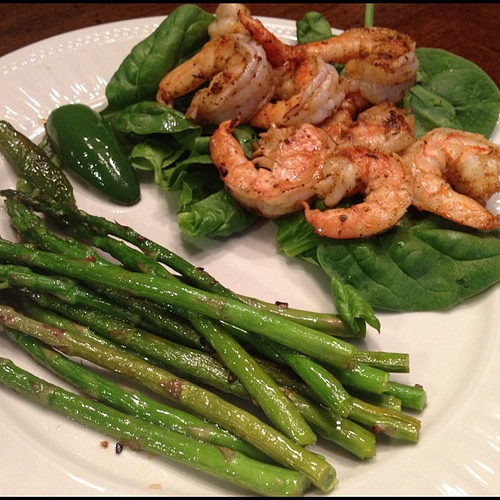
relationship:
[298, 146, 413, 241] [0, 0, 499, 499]
shrimp on plate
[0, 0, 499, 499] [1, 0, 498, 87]
plate on table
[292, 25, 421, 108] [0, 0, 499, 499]
shrimp on plate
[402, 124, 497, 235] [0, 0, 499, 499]
shrimp on plate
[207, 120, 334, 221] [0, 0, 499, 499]
shrimp on plate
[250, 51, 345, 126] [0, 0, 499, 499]
shrimp on plate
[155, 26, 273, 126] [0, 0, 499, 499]
shrimp on plate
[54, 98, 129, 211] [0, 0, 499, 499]
pepper on plate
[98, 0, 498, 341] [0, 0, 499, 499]
spinach on plate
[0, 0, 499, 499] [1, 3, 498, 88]
plate on surface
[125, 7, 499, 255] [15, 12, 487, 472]
shrimp on plate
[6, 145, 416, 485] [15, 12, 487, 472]
veggies on plate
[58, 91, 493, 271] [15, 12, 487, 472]
veggies on plate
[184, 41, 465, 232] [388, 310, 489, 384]
shrimps on plate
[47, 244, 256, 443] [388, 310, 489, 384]
asparagus on plate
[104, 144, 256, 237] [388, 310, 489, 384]
spinach on plate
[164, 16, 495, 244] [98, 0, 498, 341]
shrimp resting on spinach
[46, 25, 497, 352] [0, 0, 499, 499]
food on plate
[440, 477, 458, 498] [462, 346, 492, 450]
light on plate